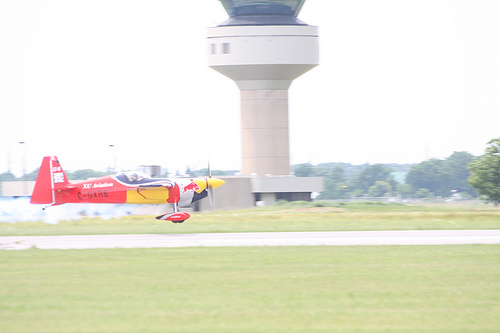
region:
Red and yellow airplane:
[33, 161, 263, 226]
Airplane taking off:
[22, 145, 269, 252]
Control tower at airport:
[208, 1, 335, 202]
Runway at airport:
[5, 218, 496, 254]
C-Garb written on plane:
[71, 187, 133, 207]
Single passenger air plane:
[26, 162, 254, 241]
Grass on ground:
[237, 257, 454, 323]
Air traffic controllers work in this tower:
[196, 5, 334, 175]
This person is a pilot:
[126, 168, 160, 210]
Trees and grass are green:
[476, 155, 498, 278]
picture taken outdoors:
[30, 28, 473, 313]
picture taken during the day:
[75, 42, 481, 263]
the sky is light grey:
[66, 32, 151, 104]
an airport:
[35, 68, 476, 270]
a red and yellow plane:
[15, 108, 266, 243]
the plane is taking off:
[25, 136, 323, 256]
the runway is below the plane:
[145, 260, 410, 295]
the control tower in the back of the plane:
[201, 35, 384, 206]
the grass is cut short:
[163, 272, 429, 327]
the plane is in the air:
[38, 151, 326, 266]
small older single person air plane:
[15, 131, 253, 237]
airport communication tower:
[194, 6, 364, 206]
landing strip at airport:
[37, 181, 447, 266]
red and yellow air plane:
[32, 141, 260, 238]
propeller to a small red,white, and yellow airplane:
[194, 156, 240, 219]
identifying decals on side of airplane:
[26, 138, 144, 223]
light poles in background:
[12, 136, 162, 185]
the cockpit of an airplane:
[103, 156, 204, 216]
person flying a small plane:
[92, 144, 192, 209]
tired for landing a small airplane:
[157, 206, 187, 238]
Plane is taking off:
[28, 153, 225, 222]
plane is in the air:
[30, 152, 235, 227]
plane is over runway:
[32, 148, 247, 232]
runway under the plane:
[2, 228, 498, 252]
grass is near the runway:
[5, 243, 499, 329]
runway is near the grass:
[5, 229, 498, 247]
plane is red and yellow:
[28, 153, 220, 232]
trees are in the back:
[311, 156, 493, 207]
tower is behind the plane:
[207, 2, 334, 208]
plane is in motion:
[20, 151, 237, 235]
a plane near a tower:
[20, 139, 234, 234]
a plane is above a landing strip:
[3, 144, 233, 259]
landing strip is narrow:
[3, 220, 498, 250]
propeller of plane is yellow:
[198, 152, 233, 203]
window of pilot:
[102, 160, 174, 187]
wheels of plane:
[146, 207, 193, 239]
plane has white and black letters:
[23, 144, 127, 215]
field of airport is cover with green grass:
[3, 202, 498, 331]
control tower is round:
[190, 4, 337, 164]